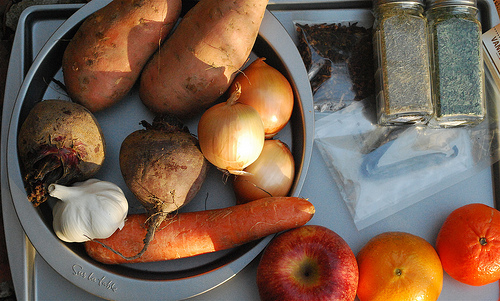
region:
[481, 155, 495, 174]
part of a table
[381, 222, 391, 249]
edge of a table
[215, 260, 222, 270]
part of a plate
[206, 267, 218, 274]
edge of a plate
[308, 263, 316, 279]
part of an apple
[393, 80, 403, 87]
edge of a jar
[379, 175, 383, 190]
part of a cloth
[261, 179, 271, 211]
part of a carrot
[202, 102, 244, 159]
White onion in dish.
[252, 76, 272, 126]
White onion in dish.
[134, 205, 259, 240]
Large carrot in dish.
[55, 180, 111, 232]
Garlic clove in dish.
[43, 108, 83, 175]
Large beet in dish.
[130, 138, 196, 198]
Large beet in dish.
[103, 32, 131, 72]
Large potato in dish.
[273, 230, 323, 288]
Apple sitting on tray.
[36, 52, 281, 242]
cake pan with vegetables in side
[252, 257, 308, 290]
red apple next to cake pan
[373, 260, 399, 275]
orange next to red apple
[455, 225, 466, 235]
tangerine by orange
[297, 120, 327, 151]
cake pan is stainless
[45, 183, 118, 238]
whole clove of garlic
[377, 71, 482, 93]
2 bottles of herbs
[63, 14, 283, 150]
orange yams in tin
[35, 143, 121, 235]
white clove of garlic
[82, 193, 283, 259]
orange and round carrot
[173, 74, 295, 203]
three onions with skin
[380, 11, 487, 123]
pepper and herb shaker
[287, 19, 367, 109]
small packet with herbs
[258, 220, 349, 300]
red and yellow apple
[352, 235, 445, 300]
orange next to apple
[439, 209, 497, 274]
tangerine next to orange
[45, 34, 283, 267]
grey tin on grey cookie tray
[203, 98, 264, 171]
a ripe yellow onion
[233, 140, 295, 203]
a ripe yellow onion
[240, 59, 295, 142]
a ripe yellow onion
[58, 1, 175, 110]
a large pink yam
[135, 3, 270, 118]
a large pink yam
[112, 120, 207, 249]
a beet that is covered in dirt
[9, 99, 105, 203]
a beet that is covered in dirt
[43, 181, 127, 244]
a head of garlic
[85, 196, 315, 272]
a picked carrot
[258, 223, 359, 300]
an apple on a tray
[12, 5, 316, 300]
silver pan with vegetables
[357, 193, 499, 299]
one orange next to an orange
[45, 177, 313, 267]
white garlic clove next to long carrot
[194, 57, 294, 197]
one onion on top of two onions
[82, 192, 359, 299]
long carrot touching apple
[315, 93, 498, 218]
plastic bag with vanilla beans